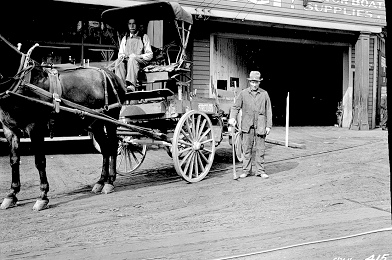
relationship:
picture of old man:
[39, 15, 356, 147] [214, 62, 285, 185]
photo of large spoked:
[39, 15, 356, 147] [171, 109, 218, 184]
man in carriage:
[105, 13, 145, 109] [104, 4, 205, 125]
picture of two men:
[39, 15, 356, 147] [115, 13, 293, 181]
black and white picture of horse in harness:
[4, 46, 337, 181] [20, 47, 134, 189]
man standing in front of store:
[105, 13, 145, 109] [193, 12, 373, 126]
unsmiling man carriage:
[117, 12, 145, 46] [104, 4, 205, 125]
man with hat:
[105, 13, 145, 109] [246, 70, 264, 82]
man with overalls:
[105, 13, 145, 109] [115, 33, 155, 93]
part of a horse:
[1, 23, 28, 83] [20, 47, 134, 189]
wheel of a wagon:
[113, 100, 161, 192] [106, 46, 258, 141]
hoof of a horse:
[61, 147, 136, 211] [7, 55, 121, 145]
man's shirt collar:
[105, 13, 145, 109] [120, 28, 138, 43]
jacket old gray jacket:
[228, 86, 274, 137] [229, 80, 289, 135]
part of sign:
[1, 23, 28, 83] [133, 1, 388, 28]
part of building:
[1, 23, 28, 83] [193, 12, 373, 126]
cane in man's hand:
[226, 113, 244, 188] [212, 103, 241, 129]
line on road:
[327, 215, 369, 258] [0, 130, 392, 233]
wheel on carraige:
[113, 100, 161, 192] [101, 21, 187, 164]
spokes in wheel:
[183, 121, 208, 153] [113, 100, 161, 192]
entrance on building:
[135, 39, 367, 163] [193, 12, 373, 126]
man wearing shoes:
[105, 13, 145, 109] [119, 80, 155, 104]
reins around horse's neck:
[4, 39, 53, 110] [0, 21, 89, 142]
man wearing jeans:
[110, 13, 156, 92] [112, 51, 145, 71]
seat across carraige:
[105, 13, 145, 109] [101, 21, 187, 164]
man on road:
[105, 13, 145, 109] [224, 139, 330, 233]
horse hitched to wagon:
[7, 55, 121, 145] [106, 46, 258, 141]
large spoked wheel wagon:
[171, 109, 218, 184] [106, 46, 258, 141]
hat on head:
[242, 53, 278, 88] [241, 65, 277, 99]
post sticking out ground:
[273, 82, 314, 182] [264, 132, 309, 173]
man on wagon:
[105, 13, 145, 109] [106, 46, 258, 141]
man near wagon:
[105, 13, 145, 109] [106, 46, 258, 141]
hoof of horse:
[61, 147, 136, 211] [7, 55, 121, 145]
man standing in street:
[105, 13, 145, 109] [249, 176, 339, 226]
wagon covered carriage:
[87, 0, 244, 185] [104, 4, 205, 125]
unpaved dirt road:
[209, 173, 313, 235] [224, 139, 330, 233]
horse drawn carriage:
[7, 55, 121, 145] [104, 4, 205, 125]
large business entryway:
[135, 39, 367, 163] [280, 35, 357, 110]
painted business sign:
[296, 5, 375, 14] [279, 2, 385, 27]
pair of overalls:
[125, 23, 169, 75] [115, 33, 155, 93]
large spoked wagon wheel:
[172, 116, 210, 177] [113, 100, 161, 192]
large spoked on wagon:
[171, 109, 218, 184] [106, 46, 258, 141]